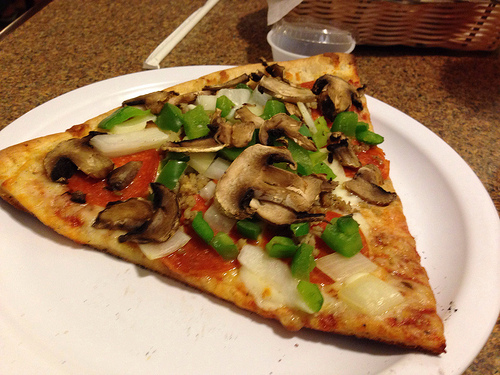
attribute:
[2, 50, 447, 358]
pizza — large, triangle shape, sliced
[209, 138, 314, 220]
mushrooms — fresh cut, cooked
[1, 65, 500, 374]
plate — white, round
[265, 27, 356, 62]
container — plastic, round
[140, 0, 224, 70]
straw — white, unopened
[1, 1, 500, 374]
table — brown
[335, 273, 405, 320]
onion — cooked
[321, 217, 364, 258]
bell pepper — fresh, sliced, green, diced